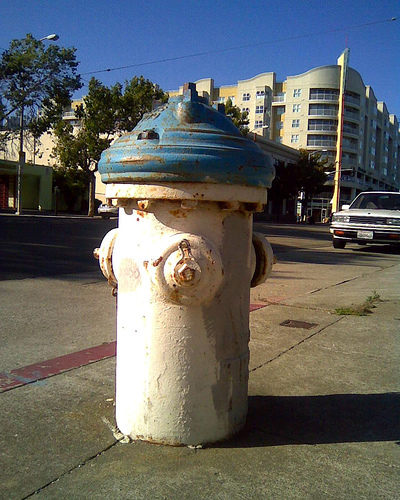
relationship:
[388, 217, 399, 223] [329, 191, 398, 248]
headlight of car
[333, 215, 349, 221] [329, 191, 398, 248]
headlight of car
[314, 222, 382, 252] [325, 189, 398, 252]
headlight of car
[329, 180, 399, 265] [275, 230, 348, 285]
car on road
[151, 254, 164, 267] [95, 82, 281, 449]
spots on fire hydrant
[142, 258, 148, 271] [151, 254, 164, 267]
spots on spots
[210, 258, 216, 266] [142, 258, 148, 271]
spots on spots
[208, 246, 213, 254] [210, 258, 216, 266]
spots on spots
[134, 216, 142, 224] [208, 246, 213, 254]
spots on spots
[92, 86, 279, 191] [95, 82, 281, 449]
top of fire hydrant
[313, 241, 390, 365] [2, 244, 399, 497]
plants on sidewalk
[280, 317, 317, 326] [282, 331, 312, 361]
cover on sidewalk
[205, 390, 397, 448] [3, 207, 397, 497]
shadow on ground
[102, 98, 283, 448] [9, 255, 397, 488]
fire hydrant on ground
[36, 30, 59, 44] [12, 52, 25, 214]
light fixture on pole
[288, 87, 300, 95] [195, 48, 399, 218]
window of building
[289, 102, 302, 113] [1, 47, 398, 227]
window of building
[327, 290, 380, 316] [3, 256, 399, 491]
grass growing in concrete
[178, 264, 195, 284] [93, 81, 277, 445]
lug nut on fire hydrant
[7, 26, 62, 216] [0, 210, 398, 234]
lamp on sidewalk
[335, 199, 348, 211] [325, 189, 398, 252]
mirror on car